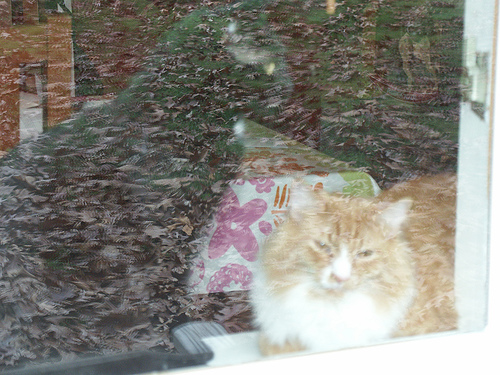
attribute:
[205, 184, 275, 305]
designs — pink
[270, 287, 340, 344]
fur — white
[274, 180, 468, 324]
cat — white, brown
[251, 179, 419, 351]
cat fur — white, brown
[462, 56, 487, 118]
latch — metal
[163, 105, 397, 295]
box — white, cardboard, with designs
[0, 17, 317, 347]
cat — black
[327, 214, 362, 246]
stripes — orange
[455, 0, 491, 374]
frame — white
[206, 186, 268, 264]
flower — pink, designs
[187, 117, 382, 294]
tablecloth — flower print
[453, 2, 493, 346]
frame — white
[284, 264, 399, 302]
whiskers — long, white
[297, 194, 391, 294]
face — cat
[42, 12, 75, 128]
bed post — wooden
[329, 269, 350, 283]
nose — white, pink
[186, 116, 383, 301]
paper — white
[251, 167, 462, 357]
cat — black, brown, white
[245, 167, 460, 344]
cat — orange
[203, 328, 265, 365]
table — white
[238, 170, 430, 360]
cat — black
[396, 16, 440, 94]
reflection — blurred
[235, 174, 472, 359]
cat — orange, white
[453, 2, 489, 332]
frame — white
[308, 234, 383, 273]
eyes — green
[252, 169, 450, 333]
cat — orange